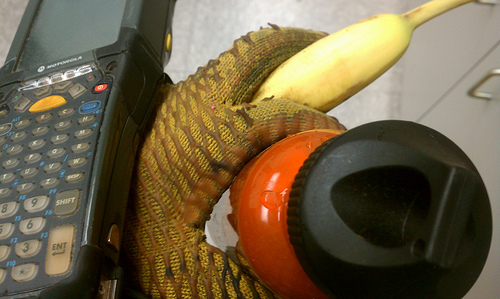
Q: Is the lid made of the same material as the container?
A: Yes, both the lid and the container are made of plastic.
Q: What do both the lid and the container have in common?
A: The material, both the lid and the container are plastic.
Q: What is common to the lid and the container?
A: The material, both the lid and the container are plastic.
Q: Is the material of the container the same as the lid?
A: Yes, both the container and the lid are made of plastic.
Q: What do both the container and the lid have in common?
A: The material, both the container and the lid are plastic.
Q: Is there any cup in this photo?
A: Yes, there is a cup.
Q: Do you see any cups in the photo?
A: Yes, there is a cup.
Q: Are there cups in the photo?
A: Yes, there is a cup.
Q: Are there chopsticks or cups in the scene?
A: Yes, there is a cup.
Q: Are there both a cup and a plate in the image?
A: No, there is a cup but no plates.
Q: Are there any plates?
A: No, there are no plates.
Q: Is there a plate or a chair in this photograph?
A: No, there are no plates or chairs.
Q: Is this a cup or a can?
A: This is a cup.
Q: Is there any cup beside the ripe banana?
A: Yes, there is a cup beside the banana.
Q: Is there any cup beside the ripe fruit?
A: Yes, there is a cup beside the banana.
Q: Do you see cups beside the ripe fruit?
A: Yes, there is a cup beside the banana.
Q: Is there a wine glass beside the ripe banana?
A: No, there is a cup beside the banana.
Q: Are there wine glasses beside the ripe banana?
A: No, there is a cup beside the banana.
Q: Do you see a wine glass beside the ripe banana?
A: No, there is a cup beside the banana.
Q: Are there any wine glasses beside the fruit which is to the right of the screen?
A: No, there is a cup beside the banana.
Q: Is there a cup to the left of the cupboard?
A: Yes, there is a cup to the left of the cupboard.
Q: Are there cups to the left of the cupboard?
A: Yes, there is a cup to the left of the cupboard.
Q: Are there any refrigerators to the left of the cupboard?
A: No, there is a cup to the left of the cupboard.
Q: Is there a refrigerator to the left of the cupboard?
A: No, there is a cup to the left of the cupboard.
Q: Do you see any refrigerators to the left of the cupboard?
A: No, there is a cup to the left of the cupboard.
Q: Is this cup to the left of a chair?
A: No, the cup is to the left of the cupboard.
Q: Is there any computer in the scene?
A: No, there are no computers.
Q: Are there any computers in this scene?
A: No, there are no computers.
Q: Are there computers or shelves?
A: No, there are no computers or shelves.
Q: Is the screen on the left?
A: Yes, the screen is on the left of the image.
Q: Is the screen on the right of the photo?
A: No, the screen is on the left of the image.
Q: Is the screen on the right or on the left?
A: The screen is on the left of the image.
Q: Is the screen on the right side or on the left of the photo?
A: The screen is on the left of the image.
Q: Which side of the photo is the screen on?
A: The screen is on the left of the image.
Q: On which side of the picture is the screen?
A: The screen is on the left of the image.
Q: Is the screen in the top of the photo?
A: Yes, the screen is in the top of the image.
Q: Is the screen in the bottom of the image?
A: No, the screen is in the top of the image.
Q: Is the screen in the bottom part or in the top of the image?
A: The screen is in the top of the image.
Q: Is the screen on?
A: Yes, the screen is on.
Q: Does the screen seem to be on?
A: Yes, the screen is on.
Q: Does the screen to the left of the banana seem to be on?
A: Yes, the screen is on.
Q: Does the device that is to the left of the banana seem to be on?
A: Yes, the screen is on.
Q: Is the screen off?
A: No, the screen is on.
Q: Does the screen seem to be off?
A: No, the screen is on.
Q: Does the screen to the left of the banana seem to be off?
A: No, the screen is on.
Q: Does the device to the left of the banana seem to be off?
A: No, the screen is on.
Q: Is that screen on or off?
A: The screen is on.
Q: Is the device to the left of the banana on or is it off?
A: The screen is on.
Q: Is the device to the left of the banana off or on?
A: The screen is on.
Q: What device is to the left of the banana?
A: The device is a screen.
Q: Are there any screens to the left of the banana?
A: Yes, there is a screen to the left of the banana.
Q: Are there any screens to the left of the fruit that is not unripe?
A: Yes, there is a screen to the left of the banana.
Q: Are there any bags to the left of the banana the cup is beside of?
A: No, there is a screen to the left of the banana.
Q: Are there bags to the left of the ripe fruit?
A: No, there is a screen to the left of the banana.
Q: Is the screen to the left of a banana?
A: Yes, the screen is to the left of a banana.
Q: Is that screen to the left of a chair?
A: No, the screen is to the left of a banana.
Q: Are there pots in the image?
A: No, there are no pots.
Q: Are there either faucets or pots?
A: No, there are no pots or faucets.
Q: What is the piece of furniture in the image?
A: The piece of furniture is a cupboard.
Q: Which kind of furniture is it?
A: The piece of furniture is a cupboard.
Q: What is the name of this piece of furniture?
A: That is a cupboard.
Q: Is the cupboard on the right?
A: Yes, the cupboard is on the right of the image.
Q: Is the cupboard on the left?
A: No, the cupboard is on the right of the image.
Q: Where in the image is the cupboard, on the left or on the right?
A: The cupboard is on the right of the image.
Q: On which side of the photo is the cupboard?
A: The cupboard is on the right of the image.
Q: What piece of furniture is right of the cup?
A: The piece of furniture is a cupboard.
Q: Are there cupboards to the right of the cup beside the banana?
A: Yes, there is a cupboard to the right of the cup.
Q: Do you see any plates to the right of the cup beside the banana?
A: No, there is a cupboard to the right of the cup.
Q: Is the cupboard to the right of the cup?
A: Yes, the cupboard is to the right of the cup.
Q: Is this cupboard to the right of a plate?
A: No, the cupboard is to the right of the cup.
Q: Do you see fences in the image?
A: No, there are no fences.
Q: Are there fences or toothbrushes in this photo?
A: No, there are no fences or toothbrushes.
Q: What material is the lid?
A: The lid is made of plastic.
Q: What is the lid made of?
A: The lid is made of plastic.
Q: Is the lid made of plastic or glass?
A: The lid is made of plastic.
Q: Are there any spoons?
A: No, there are no spoons.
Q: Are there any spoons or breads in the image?
A: No, there are no spoons or breads.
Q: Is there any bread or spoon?
A: No, there are no spoons or breads.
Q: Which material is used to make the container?
A: The container is made of plastic.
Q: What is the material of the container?
A: The container is made of plastic.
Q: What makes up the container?
A: The container is made of plastic.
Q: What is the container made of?
A: The container is made of plastic.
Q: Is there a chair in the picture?
A: No, there are no chairs.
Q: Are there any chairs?
A: No, there are no chairs.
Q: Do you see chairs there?
A: No, there are no chairs.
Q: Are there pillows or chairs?
A: No, there are no chairs or pillows.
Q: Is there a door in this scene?
A: Yes, there is a door.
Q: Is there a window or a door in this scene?
A: Yes, there is a door.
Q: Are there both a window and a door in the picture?
A: No, there is a door but no windows.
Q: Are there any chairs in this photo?
A: No, there are no chairs.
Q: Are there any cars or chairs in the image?
A: No, there are no chairs or cars.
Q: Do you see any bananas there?
A: Yes, there is a banana.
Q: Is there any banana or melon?
A: Yes, there is a banana.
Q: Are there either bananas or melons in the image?
A: Yes, there is a banana.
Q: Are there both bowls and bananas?
A: No, there is a banana but no bowls.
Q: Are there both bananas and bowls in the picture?
A: No, there is a banana but no bowls.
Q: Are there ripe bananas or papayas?
A: Yes, there is a ripe banana.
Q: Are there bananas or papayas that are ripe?
A: Yes, the banana is ripe.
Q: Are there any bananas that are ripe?
A: Yes, there is a ripe banana.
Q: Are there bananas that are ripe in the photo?
A: Yes, there is a ripe banana.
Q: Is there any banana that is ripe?
A: Yes, there is a banana that is ripe.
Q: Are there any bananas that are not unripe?
A: Yes, there is an ripe banana.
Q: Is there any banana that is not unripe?
A: Yes, there is an ripe banana.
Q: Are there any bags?
A: No, there are no bags.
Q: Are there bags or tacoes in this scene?
A: No, there are no bags or tacoes.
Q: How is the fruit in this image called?
A: The fruit is a banana.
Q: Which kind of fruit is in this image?
A: The fruit is a banana.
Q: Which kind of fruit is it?
A: The fruit is a banana.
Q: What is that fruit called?
A: This is a banana.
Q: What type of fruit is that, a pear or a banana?
A: This is a banana.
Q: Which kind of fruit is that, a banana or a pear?
A: This is a banana.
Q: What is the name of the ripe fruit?
A: The fruit is a banana.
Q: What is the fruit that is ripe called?
A: The fruit is a banana.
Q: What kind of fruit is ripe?
A: The fruit is a banana.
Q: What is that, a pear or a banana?
A: That is a banana.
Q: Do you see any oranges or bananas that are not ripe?
A: No, there is a banana but it is ripe.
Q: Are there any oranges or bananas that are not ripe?
A: No, there is a banana but it is ripe.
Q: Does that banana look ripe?
A: Yes, the banana is ripe.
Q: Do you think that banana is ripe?
A: Yes, the banana is ripe.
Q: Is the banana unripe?
A: No, the banana is ripe.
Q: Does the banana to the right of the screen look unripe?
A: No, the banana is ripe.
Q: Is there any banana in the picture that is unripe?
A: No, there is a banana but it is ripe.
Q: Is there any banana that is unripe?
A: No, there is a banana but it is ripe.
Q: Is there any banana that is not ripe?
A: No, there is a banana but it is ripe.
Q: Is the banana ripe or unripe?
A: The banana is ripe.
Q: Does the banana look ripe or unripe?
A: The banana is ripe.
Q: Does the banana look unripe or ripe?
A: The banana is ripe.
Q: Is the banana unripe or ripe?
A: The banana is ripe.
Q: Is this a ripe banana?
A: Yes, this is a ripe banana.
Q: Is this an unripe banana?
A: No, this is a ripe banana.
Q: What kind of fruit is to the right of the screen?
A: The fruit is a banana.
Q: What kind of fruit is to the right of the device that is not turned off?
A: The fruit is a banana.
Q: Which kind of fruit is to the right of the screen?
A: The fruit is a banana.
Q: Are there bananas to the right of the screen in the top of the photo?
A: Yes, there is a banana to the right of the screen.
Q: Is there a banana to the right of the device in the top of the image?
A: Yes, there is a banana to the right of the screen.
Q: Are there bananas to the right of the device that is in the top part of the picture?
A: Yes, there is a banana to the right of the screen.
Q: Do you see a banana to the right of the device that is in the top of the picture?
A: Yes, there is a banana to the right of the screen.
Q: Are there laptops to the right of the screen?
A: No, there is a banana to the right of the screen.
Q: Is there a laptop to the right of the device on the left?
A: No, there is a banana to the right of the screen.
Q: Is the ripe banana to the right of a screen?
A: Yes, the banana is to the right of a screen.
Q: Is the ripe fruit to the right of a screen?
A: Yes, the banana is to the right of a screen.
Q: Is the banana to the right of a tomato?
A: No, the banana is to the right of a screen.